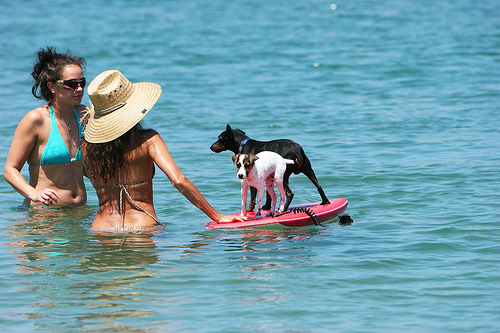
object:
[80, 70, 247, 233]
person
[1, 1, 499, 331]
water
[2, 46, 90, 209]
person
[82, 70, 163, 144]
hat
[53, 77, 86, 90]
sunglasses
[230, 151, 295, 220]
dog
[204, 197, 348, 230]
surfboard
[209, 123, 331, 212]
dog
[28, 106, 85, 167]
bikini top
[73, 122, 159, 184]
hair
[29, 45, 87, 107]
hair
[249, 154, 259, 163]
ear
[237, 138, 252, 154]
collar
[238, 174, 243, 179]
nose